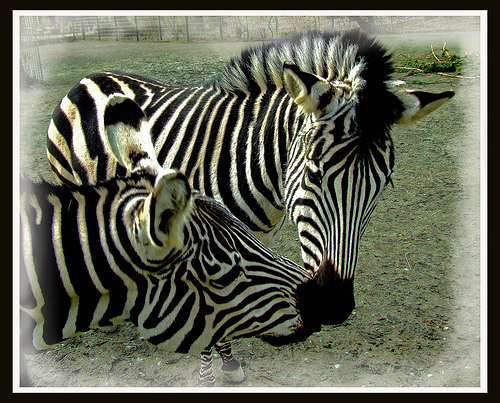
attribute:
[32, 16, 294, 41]
fence — wire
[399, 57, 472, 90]
sticks — broken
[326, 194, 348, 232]
stripes — black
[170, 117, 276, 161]
stripes — white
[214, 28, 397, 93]
hair — standing up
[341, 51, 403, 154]
hair — black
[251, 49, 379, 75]
hair — white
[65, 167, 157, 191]
hair — very little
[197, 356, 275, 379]
feet — white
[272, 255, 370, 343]
noses — black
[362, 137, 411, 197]
eyelashes — black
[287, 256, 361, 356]
nose — black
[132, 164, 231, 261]
ear — furry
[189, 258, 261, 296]
eye — black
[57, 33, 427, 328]
zebra — black, white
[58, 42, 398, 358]
zebra — standing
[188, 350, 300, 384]
hoof — white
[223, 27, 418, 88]
zebra mane — white, black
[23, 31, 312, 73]
fence — chainlink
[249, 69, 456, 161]
ears — big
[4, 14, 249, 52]
fence — long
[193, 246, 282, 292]
eye — big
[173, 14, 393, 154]
mane — black and white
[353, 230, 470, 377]
grass — green